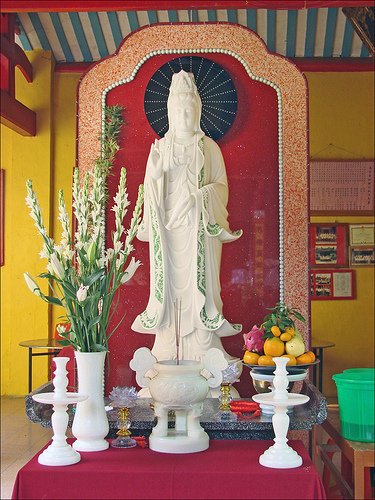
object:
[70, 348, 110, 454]
vase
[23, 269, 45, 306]
flowers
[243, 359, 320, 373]
bowl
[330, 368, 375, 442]
tub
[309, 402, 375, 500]
table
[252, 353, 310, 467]
candle holder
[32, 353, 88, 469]
candle holder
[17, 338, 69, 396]
table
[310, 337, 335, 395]
table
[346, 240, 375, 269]
pictures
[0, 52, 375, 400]
wall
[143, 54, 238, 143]
medaillon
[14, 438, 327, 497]
cloth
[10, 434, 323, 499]
table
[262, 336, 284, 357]
orange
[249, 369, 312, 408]
pedestal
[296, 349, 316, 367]
fruit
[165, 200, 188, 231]
frisbee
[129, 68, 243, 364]
someone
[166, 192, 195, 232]
hands